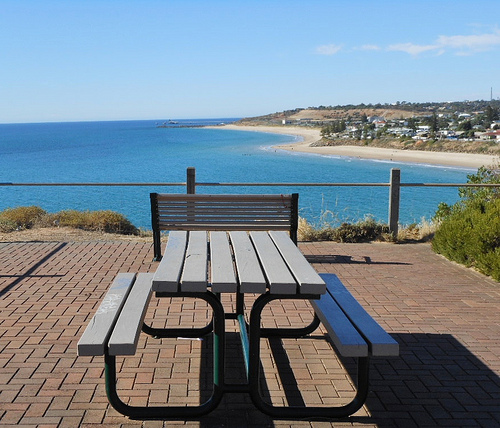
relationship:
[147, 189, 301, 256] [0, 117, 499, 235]
bench facing water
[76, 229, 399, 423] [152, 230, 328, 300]
table has top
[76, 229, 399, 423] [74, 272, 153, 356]
table has seat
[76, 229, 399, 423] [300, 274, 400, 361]
table has seat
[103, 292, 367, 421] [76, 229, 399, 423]
pipe beneath table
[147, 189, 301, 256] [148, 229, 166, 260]
bench has leg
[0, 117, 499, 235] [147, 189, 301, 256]
water in front of bench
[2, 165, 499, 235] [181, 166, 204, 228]
fence has post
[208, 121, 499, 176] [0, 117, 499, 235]
beach beside water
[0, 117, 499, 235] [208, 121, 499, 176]
water on beach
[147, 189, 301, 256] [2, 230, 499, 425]
bench on balcony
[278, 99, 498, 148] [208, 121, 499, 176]
houses are on beach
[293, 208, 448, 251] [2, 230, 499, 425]
bushes are on balcony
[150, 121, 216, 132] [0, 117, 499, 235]
rocks are in water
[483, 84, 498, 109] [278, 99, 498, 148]
tower by houses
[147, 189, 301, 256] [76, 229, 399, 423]
bench beside table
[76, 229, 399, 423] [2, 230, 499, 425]
table on balcony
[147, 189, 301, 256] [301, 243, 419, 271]
bench has shadow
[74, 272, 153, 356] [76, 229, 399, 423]
seat beside table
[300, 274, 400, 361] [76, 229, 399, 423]
seat beside table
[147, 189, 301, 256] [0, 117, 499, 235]
bench overlooking water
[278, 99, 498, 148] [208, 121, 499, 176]
houses are beside beach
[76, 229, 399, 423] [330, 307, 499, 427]
table has shadow